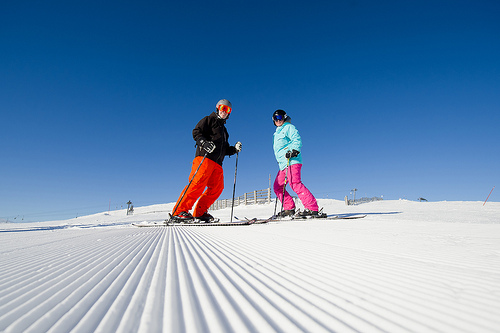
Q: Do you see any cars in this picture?
A: No, there are no cars.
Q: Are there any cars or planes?
A: No, there are no cars or planes.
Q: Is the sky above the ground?
A: Yes, the sky is above the ground.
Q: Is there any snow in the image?
A: Yes, there is snow.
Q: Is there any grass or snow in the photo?
A: Yes, there is snow.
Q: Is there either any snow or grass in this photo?
A: Yes, there is snow.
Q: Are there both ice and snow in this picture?
A: No, there is snow but no ice.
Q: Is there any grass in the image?
A: No, there is no grass.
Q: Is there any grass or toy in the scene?
A: No, there are no grass or toys.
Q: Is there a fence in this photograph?
A: Yes, there is a fence.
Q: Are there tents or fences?
A: Yes, there is a fence.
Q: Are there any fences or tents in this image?
A: Yes, there is a fence.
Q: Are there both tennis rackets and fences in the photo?
A: No, there is a fence but no rackets.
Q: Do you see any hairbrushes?
A: No, there are no hairbrushes.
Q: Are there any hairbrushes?
A: No, there are no hairbrushes.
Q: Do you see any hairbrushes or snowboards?
A: No, there are no hairbrushes or snowboards.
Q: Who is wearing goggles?
A: The man is wearing goggles.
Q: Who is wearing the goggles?
A: The man is wearing goggles.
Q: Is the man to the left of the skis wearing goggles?
A: Yes, the man is wearing goggles.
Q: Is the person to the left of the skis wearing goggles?
A: Yes, the man is wearing goggles.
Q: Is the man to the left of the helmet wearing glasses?
A: No, the man is wearing goggles.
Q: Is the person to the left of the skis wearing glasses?
A: No, the man is wearing goggles.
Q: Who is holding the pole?
A: The man is holding the pole.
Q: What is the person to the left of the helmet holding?
A: The man is holding the pole.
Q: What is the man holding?
A: The man is holding the pole.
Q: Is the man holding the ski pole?
A: Yes, the man is holding the pole.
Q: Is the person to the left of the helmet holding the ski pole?
A: Yes, the man is holding the pole.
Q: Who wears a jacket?
A: The man wears a jacket.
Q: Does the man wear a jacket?
A: Yes, the man wears a jacket.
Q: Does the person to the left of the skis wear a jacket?
A: Yes, the man wears a jacket.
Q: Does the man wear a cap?
A: No, the man wears a jacket.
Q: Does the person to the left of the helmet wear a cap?
A: No, the man wears a jacket.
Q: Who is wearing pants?
A: The man is wearing pants.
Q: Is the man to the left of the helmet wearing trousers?
A: Yes, the man is wearing trousers.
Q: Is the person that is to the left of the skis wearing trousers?
A: Yes, the man is wearing trousers.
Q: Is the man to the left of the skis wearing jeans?
A: No, the man is wearing trousers.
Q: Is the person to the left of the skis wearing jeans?
A: No, the man is wearing trousers.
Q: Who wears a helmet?
A: The man wears a helmet.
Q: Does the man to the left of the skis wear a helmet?
A: Yes, the man wears a helmet.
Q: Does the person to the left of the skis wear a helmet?
A: Yes, the man wears a helmet.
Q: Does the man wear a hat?
A: No, the man wears a helmet.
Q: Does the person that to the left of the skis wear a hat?
A: No, the man wears a helmet.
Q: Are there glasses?
A: No, there are no glasses.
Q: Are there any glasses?
A: No, there are no glasses.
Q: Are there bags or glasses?
A: No, there are no glasses or bags.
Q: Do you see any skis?
A: Yes, there are skis.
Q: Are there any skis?
A: Yes, there are skis.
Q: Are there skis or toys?
A: Yes, there are skis.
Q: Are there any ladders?
A: No, there are no ladders.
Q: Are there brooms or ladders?
A: No, there are no ladders or brooms.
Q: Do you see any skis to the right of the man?
A: Yes, there are skis to the right of the man.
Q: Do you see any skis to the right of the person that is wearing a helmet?
A: Yes, there are skis to the right of the man.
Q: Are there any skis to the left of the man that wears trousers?
A: No, the skis are to the right of the man.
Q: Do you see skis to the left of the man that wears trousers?
A: No, the skis are to the right of the man.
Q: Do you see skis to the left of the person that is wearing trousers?
A: No, the skis are to the right of the man.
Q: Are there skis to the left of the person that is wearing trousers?
A: No, the skis are to the right of the man.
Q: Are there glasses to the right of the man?
A: No, there are skis to the right of the man.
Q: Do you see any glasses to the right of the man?
A: No, there are skis to the right of the man.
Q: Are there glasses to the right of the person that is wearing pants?
A: No, there are skis to the right of the man.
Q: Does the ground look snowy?
A: Yes, the ground is snowy.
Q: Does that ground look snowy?
A: Yes, the ground is snowy.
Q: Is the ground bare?
A: No, the ground is snowy.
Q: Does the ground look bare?
A: No, the ground is snowy.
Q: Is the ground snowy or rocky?
A: The ground is snowy.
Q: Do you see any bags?
A: No, there are no bags.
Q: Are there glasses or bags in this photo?
A: No, there are no bags or glasses.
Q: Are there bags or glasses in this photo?
A: No, there are no bags or glasses.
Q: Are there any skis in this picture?
A: Yes, there are skis.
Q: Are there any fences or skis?
A: Yes, there are skis.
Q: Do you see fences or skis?
A: Yes, there are skis.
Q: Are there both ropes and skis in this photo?
A: No, there are skis but no ropes.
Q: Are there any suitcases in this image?
A: No, there are no suitcases.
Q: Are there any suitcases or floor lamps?
A: No, there are no suitcases or floor lamps.